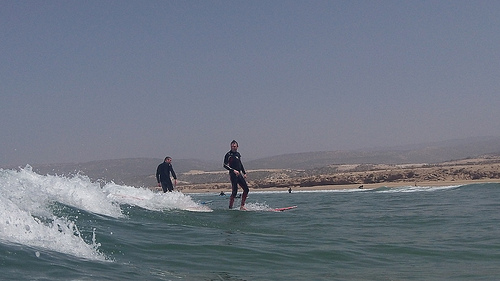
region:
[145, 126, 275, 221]
the two men are surfing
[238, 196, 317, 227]
the surfboard is pink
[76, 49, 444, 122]
the sky is clear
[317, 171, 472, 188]
there are people on the beach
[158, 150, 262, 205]
the guys are wet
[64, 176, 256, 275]
there are waves in the sea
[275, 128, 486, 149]
there are hills in the background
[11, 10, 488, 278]
the photo was taken during the day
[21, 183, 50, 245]
the water is white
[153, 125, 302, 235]
the two people are males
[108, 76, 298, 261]
two men surfing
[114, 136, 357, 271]
two men in water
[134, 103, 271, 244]
two men in black wet suits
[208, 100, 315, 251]
one man on red surfboard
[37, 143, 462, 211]
mountains in background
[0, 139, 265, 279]
white water behind men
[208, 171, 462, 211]
people on beach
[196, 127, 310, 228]
one man looking back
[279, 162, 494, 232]
waves breaking near beach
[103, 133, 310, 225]
two men near each other in water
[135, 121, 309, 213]
two surfers wearing wetsuits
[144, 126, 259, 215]
two black wet suites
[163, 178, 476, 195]
a few people on the beach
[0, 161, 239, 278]
a white cresting wave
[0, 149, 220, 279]
a big wave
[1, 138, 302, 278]
a wave on the ocean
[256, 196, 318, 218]
a red surfboard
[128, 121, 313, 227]
two people surfing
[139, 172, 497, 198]
a long sandy beach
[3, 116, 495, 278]
grey blue ocean water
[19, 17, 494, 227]
Picture taken outside.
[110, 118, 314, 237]
People surfing.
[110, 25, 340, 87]
The sky is light blue.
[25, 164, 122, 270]
The waves are white.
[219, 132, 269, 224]
The man is facing the camera.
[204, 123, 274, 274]
The man is wearing a body suit.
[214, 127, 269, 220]
The body suit is black.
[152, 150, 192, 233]
The man's back is facing the camera.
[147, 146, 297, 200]
Both men are verticle.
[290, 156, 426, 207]
The beach is in the background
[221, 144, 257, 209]
surfer in black wetsuit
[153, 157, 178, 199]
surfer standing on board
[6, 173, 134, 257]
small breaking wave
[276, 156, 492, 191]
shoreline along sandy beach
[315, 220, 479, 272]
grey unclear water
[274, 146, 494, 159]
hills or mountains next to beach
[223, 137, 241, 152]
man's face looking at wave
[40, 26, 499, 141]
clear skies nice weather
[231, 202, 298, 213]
pink surfboard in water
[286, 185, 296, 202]
person on the beach